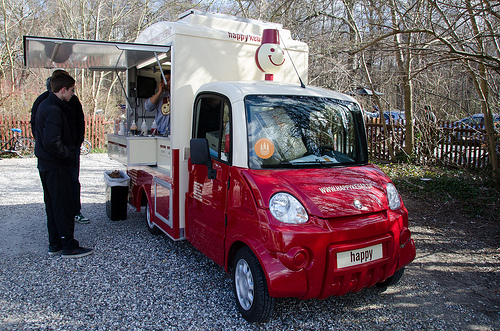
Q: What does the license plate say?
A: Happy.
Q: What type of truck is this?
A: A food truck.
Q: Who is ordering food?
A: Two men.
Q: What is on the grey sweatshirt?
A: A happy face.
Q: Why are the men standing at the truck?
A: To order food.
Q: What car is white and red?
A: The truck.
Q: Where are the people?
A: Standing by the truck.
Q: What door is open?
A: The side door.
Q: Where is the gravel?
A: On a road.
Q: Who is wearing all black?
A: A man.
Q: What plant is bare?
A: The tree.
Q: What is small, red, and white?
A: A small truck.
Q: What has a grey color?
A: The road.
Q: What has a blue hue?
A: The sky.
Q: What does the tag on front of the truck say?
A: Happy.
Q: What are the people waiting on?
A: Food.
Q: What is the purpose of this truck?
A: To sell food.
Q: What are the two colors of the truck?
A: Red and white.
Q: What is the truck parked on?
A: Gravel.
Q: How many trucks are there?
A: One.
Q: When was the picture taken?
A: Daytime.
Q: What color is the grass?
A: Green.